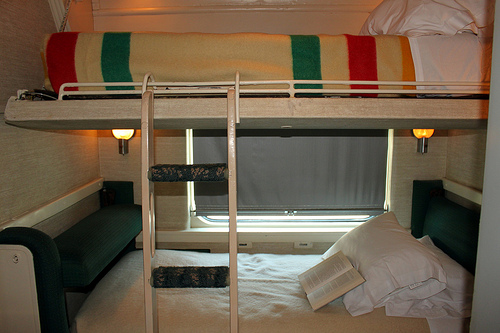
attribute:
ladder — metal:
[119, 71, 273, 325]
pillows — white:
[336, 193, 432, 327]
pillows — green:
[58, 206, 150, 289]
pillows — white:
[114, 226, 484, 331]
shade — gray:
[243, 137, 383, 220]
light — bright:
[98, 122, 141, 165]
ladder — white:
[116, 77, 257, 326]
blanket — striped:
[160, 101, 385, 144]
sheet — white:
[406, 50, 458, 88]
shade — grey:
[265, 159, 314, 238]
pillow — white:
[364, 242, 412, 281]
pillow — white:
[399, 283, 441, 333]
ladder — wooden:
[142, 101, 258, 311]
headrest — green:
[44, 191, 134, 270]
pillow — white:
[358, 258, 435, 293]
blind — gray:
[244, 194, 347, 234]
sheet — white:
[404, 52, 478, 83]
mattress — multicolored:
[27, 24, 484, 109]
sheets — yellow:
[56, 29, 399, 95]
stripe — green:
[288, 30, 328, 98]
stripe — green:
[102, 29, 140, 91]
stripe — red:
[343, 32, 380, 81]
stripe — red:
[48, 30, 78, 100]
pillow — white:
[318, 206, 437, 314]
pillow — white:
[374, 218, 471, 327]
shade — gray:
[190, 132, 388, 221]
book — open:
[291, 242, 361, 312]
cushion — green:
[22, 171, 144, 286]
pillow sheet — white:
[329, 197, 441, 313]